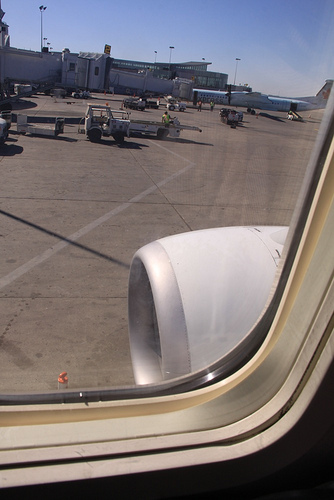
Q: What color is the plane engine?
A: Silver.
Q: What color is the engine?
A: White.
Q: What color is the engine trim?
A: Silver.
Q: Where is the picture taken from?
A: Airplane.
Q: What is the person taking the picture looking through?
A: Airplane window.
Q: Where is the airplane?
A: Airport.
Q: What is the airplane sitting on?
A: Grey asphalt.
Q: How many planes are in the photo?
A: Two.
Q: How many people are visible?
A: Three.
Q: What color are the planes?
A: White.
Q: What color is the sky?
A: Blue.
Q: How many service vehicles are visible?
A: One.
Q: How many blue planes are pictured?
A: 1.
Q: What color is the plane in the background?
A: Blue.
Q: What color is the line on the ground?
A: White.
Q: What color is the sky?
A: Blue.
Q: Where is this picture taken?
A: Airport.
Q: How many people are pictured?
A: 3.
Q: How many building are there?
A: One.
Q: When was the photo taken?
A: Day time.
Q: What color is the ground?
A: Gray.